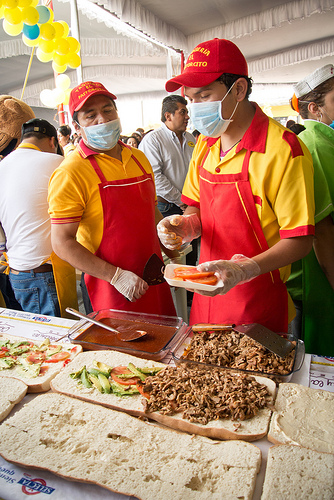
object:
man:
[156, 36, 316, 335]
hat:
[164, 37, 250, 97]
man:
[45, 80, 179, 318]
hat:
[67, 79, 119, 117]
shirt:
[180, 102, 317, 324]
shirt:
[45, 137, 158, 254]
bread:
[1, 371, 30, 420]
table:
[0, 307, 334, 499]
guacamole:
[106, 429, 131, 443]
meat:
[231, 419, 240, 431]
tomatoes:
[171, 266, 216, 279]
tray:
[162, 262, 225, 292]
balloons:
[23, 23, 44, 46]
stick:
[20, 47, 40, 107]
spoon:
[64, 306, 148, 344]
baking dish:
[66, 306, 184, 362]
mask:
[185, 81, 239, 138]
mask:
[73, 117, 122, 152]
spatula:
[190, 320, 296, 359]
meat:
[179, 324, 297, 388]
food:
[98, 373, 113, 393]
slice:
[0, 386, 265, 499]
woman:
[286, 64, 334, 359]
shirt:
[295, 119, 333, 356]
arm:
[234, 149, 315, 281]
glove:
[109, 266, 148, 303]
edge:
[0, 305, 78, 324]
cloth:
[0, 306, 334, 499]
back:
[0, 141, 65, 273]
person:
[0, 117, 66, 318]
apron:
[188, 144, 288, 336]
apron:
[80, 154, 177, 316]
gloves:
[155, 212, 202, 251]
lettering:
[201, 59, 208, 67]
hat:
[19, 116, 67, 157]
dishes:
[172, 323, 306, 382]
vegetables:
[44, 349, 70, 364]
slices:
[0, 332, 83, 393]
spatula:
[141, 251, 166, 288]